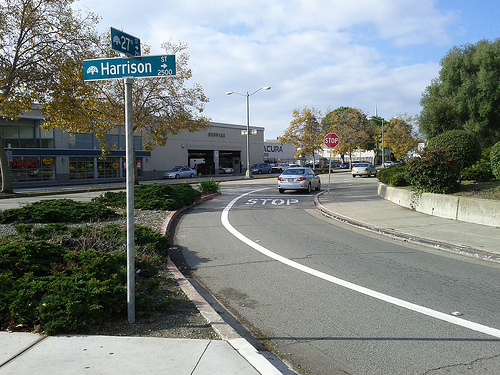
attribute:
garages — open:
[183, 143, 246, 178]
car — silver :
[270, 161, 337, 208]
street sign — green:
[80, 52, 177, 81]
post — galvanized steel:
[120, 76, 138, 323]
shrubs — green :
[0, 179, 222, 329]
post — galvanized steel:
[327, 147, 334, 192]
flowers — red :
[421, 149, 431, 156]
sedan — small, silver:
[277, 164, 322, 194]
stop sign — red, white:
[320, 129, 343, 152]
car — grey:
[274, 164, 325, 199]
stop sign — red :
[322, 130, 338, 149]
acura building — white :
[261, 139, 293, 158]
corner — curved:
[9, 176, 250, 372]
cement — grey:
[0, 331, 254, 372]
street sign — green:
[109, 27, 142, 57]